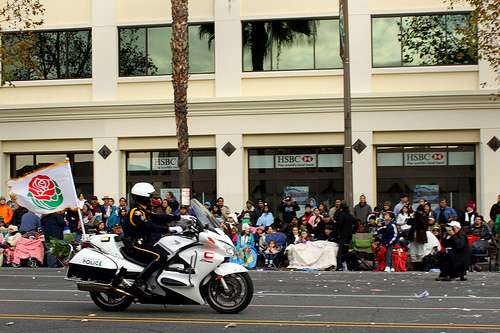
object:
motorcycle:
[64, 197, 256, 311]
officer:
[119, 180, 197, 300]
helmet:
[130, 181, 158, 206]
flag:
[5, 157, 87, 240]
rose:
[27, 174, 57, 201]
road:
[1, 266, 500, 333]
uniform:
[120, 207, 197, 295]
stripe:
[133, 243, 159, 261]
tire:
[203, 268, 256, 315]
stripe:
[0, 312, 499, 330]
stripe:
[0, 287, 500, 301]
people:
[374, 209, 402, 274]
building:
[1, 0, 499, 230]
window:
[239, 15, 346, 75]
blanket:
[284, 240, 339, 271]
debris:
[414, 290, 431, 300]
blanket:
[12, 235, 45, 265]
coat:
[373, 244, 409, 272]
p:
[81, 258, 87, 264]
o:
[85, 260, 90, 264]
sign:
[273, 152, 318, 168]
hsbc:
[278, 154, 300, 163]